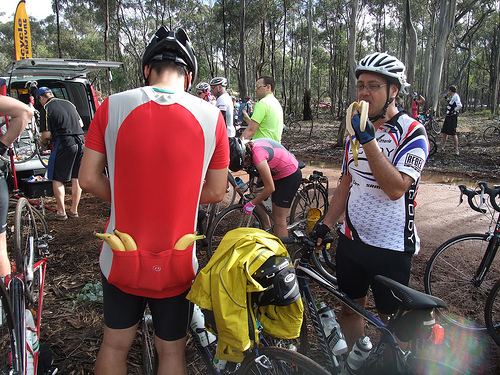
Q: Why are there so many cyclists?
A: Upcoming competition.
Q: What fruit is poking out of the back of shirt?
A: Bananas.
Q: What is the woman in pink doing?
A: Examining the bicycle.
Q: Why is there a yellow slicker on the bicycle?
A: Case of rain.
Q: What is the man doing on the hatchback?
A: Repairing bicycle.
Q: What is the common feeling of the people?
A: Psyched to race.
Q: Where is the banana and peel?
A: Hand man eating.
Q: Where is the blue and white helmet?
A: On the head.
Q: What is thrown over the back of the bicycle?
A: Yellow rain jacket.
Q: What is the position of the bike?
A: Upside down.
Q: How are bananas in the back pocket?
A: Yellow.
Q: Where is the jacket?
A: On the bike.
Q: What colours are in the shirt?
A: Red, black, blue and white shirt.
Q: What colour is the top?
A: Easter egg green and pink.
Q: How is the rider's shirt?
A: It is red and white.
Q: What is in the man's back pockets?
A: Bananas.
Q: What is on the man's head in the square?
A: A helmet.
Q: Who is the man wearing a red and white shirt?
A: A bicyclist.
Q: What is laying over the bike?
A: A yellow jacket.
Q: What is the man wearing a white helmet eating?
A: A banana.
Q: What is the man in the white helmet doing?
A: Eating a banana.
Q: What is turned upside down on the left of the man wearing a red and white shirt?
A: A bike.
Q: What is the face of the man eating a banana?
A: Eyeglasses.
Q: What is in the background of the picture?
A: Trees.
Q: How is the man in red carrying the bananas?
A: Pockets on the back of the athletic shirt.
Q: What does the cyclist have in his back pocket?
A: Banana.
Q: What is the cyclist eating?
A: Banana.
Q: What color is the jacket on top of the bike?
A: Yellow.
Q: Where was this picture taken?
A: Bike race.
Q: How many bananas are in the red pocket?
A: Three.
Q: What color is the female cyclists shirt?
A: Pink.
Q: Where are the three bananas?
A: Back pocket.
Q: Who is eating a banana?
A: Cyclist.